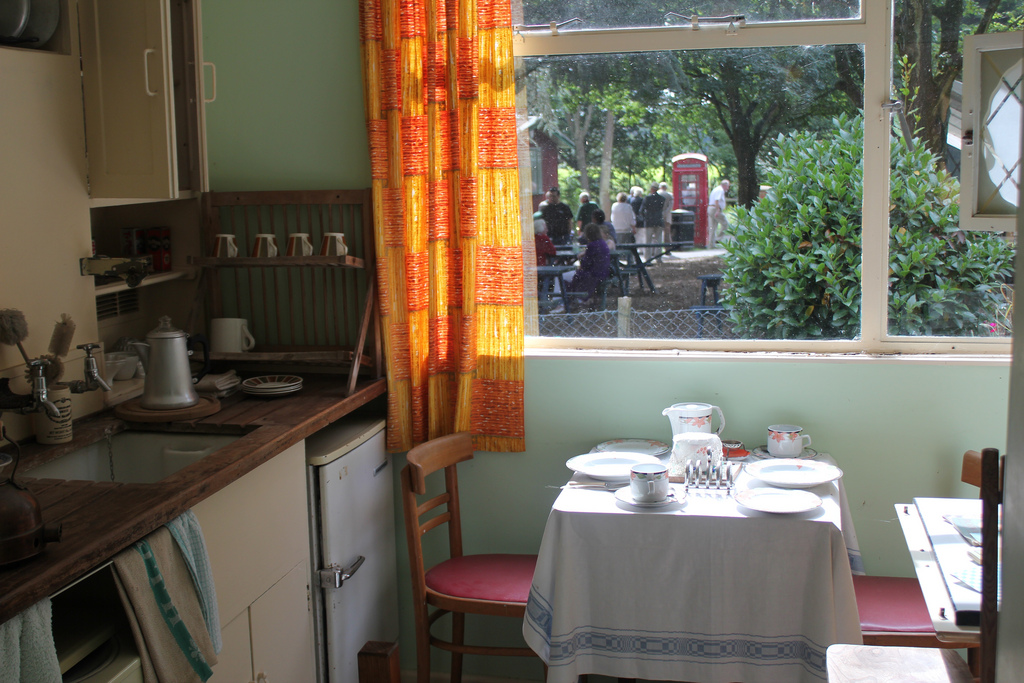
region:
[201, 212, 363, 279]
a bunch of mug cups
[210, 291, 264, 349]
a large white mug cup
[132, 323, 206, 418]
a large silver cup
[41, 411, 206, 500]
a sink that is small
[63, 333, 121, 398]
a faucet that is silver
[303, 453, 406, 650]
a small white fridge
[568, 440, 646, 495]
a plate that is white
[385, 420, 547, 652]
a small wooden chair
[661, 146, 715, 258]
a red telephone booth is outside the window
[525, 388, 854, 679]
a kitchen table is set for two people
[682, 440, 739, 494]
a toast caddy is on the table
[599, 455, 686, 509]
a cup and saucer is on the side of the plate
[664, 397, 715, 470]
a pitcher is in the middle of the table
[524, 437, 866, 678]
the tablecloth is white with a blue border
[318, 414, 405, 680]
a refridgerator is under the counter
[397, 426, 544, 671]
the wooden chair has a red seat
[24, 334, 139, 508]
the faucets are over the sink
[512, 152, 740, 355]
people are standing outside the window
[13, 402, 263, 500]
Kitchen sink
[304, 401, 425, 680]
Small white refrigerator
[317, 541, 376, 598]
Silver handle on small refrigerator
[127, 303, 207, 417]
Coffee pot on kitchen counter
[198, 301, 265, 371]
Coffee cup on kitchen counter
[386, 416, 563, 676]
Wooden kitchen chair with red seat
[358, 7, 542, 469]
Orange and yellow curtains in kitchen window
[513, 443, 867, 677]
Kitchen table with white tablecloth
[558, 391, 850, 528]
Dishes on kitchen table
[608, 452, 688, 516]
Cup and saucer on kitchen table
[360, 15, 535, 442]
yellow and orange curtains on the window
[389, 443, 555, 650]
a red chair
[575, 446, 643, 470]
a plate on the table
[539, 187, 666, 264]
people standing outside the window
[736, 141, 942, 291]
a bush outside the window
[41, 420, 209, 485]
the sink on the counter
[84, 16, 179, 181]
a white cupboard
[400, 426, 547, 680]
Wooden chair near table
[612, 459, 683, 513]
Saucer and cup on table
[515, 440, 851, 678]
White tablecloth on table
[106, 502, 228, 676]
Towel hanging from kitchen counter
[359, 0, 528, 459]
Open drape on kitchen window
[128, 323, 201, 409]
Metal coffee pot on counter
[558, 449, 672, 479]
White plate on kitchen table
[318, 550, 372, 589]
Metal latch on kitchen icebox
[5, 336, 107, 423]
Metal faucets over kitchen sink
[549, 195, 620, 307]
People sitting on the bench.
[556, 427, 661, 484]
White plates on the table.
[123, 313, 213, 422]
A tea kettle on the counter.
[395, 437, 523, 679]
The chair is wooden.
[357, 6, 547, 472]
The curtain is orange and red.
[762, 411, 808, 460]
A cup on the table.